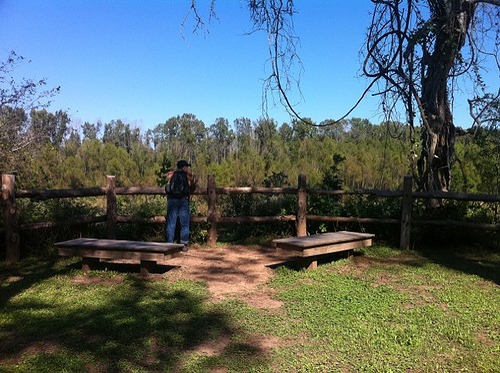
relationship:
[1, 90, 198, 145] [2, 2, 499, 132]
clouds in sky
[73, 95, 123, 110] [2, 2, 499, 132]
clouds in sky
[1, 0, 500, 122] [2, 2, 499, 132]
clouds in sky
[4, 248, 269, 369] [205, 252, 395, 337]
shadows on ground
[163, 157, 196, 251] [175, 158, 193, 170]
man wearing hat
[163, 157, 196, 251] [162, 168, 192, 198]
man has backpack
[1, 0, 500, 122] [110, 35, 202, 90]
clouds in sky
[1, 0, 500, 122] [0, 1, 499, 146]
clouds in sky